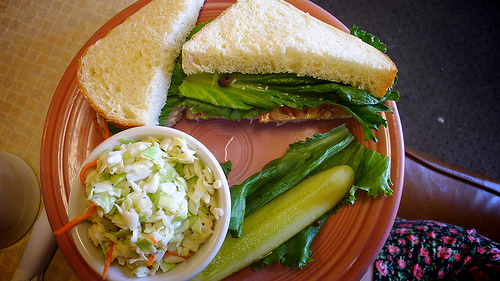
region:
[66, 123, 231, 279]
A small white cup of cole slaw.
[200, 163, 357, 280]
A green pickle spear.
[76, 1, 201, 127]
Half of a white sandwich pointing up.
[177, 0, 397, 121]
Half of a triangle sandwich horizontal on a plate.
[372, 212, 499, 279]
Floral print on a clothing item someone is wearing.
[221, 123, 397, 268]
Dark green lettuce under a pickle.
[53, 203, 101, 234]
Orange carrot sticking out the furthest in the cole slaw.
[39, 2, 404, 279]
An orange plate.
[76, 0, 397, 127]
Two halves of a white bread sandwich.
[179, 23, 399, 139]
Green lettuce sticking out of the horizonal sandwich half.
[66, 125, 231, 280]
cole slaw inside a small white bowl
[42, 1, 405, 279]
bowl on top of an orange plate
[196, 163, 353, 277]
pickle spear on top of lettuce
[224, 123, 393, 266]
lettuce on top of a plate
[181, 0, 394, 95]
slice of white bread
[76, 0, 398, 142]
sandwich on top of a plate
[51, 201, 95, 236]
carrot mixed with cole slaw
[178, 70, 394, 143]
lettuce under bread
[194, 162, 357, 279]
pickle spear next to bowl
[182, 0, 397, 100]
bread next to bread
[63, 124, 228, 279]
a white bowl of cole slaw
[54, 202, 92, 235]
a piece of shredded carrot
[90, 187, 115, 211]
a piece of chopped cabbage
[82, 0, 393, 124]
a sandwich on white bread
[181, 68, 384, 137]
a piece of green lettuce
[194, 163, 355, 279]
a pickel spear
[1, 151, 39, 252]
a garbage pail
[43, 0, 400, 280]
a salmon colored plate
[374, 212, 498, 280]
a pink and green flower print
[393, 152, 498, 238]
a section of a brown couch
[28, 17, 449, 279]
a red plate of food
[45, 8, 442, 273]
a red plate on a table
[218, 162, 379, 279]
a pickle on a plate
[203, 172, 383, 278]
a pickle on a red plate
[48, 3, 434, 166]
a sandwich on a plate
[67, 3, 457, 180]
a sandwich on a red plate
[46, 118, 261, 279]
coleslaw in a white bowl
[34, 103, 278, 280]
coleslaw in a white bowl on a plate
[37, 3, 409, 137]
a sandwich cut in half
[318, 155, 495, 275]
a flowered dress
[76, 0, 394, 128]
two halves of a sandwich in an orange plate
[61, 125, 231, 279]
coleslaw in a white bowl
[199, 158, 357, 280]
a long pickle slice on a plate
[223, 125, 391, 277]
a lettuce leaf on an orange plate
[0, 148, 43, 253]
an empty cup on a counter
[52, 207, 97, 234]
a small stick of carrot in a coleslaw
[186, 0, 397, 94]
a loaf of white bread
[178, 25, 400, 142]
lettuce in a sandwich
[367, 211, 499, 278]
a black shirt with pink flowers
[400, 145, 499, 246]
edge of a brown leather couch